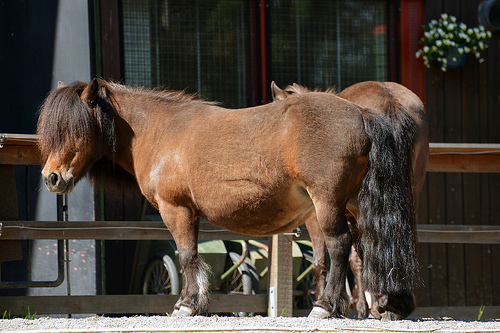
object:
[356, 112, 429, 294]
tail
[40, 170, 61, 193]
nose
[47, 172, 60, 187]
nostril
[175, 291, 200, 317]
hoof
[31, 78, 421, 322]
horse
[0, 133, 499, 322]
rail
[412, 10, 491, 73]
plant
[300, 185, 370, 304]
leg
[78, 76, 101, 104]
ear